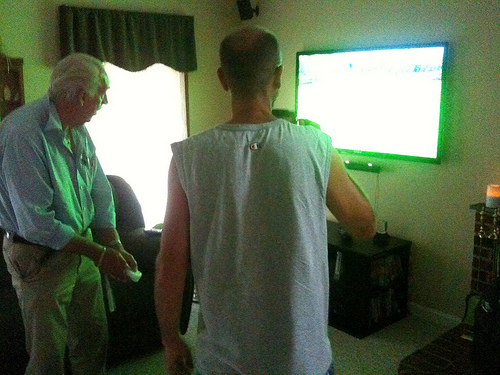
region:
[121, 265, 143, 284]
White Nintendo Wii controller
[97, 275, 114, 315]
Strap of the Nintendo Wii controller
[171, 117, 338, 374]
Grey sleeveless champion shirt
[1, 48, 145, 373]
Cute old man playing wii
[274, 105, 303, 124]
Black mug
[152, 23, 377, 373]
Middle age balding man observing the tv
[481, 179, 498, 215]
I lit candle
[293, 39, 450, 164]
A pretty big tv mounted on the wall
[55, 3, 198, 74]
Short green curtains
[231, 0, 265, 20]
Black speakers mounted on the wall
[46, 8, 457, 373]
two men standing inside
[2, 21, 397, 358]
two men standing up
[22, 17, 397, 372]
two men playing the wii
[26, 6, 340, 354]
two men playing the wii inside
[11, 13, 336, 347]
two men holding wii remotes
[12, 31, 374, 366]
two men holding white wii remotes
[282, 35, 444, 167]
a tv mounted on the wall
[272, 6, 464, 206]
a television mounted on the wall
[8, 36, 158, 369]
an old man playing the wii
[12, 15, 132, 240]
a man with white hair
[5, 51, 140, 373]
man playing the wii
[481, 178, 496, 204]
candle on the mantle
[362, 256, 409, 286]
movies on the shelf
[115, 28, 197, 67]
curtain on the window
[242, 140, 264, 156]
logo on the gray shirt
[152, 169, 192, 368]
arm on the man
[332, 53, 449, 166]
bight screen on the tv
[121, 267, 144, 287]
wii remote in the mans hand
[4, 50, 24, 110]
brown shelf on the wall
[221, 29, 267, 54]
bald spot on top of the head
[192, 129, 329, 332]
A vest in the photo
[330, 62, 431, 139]
A screen in the photo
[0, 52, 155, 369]
An old man in the photo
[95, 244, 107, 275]
A bracelet in the photo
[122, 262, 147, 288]
A joystick in the hand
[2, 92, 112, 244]
A blue shirt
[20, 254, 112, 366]
A trouser in the photo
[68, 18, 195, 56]
Curtain on the door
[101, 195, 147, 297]
Playing a video game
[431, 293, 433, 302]
part of a wall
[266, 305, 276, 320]
part of a shirt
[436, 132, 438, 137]
part of a screen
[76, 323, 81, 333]
part of a trouser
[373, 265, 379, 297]
part of a table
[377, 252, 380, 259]
edge of a table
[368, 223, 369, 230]
part of an elbow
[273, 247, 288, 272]
part of a shirt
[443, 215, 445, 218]
side of a wall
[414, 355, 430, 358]
part of a brick